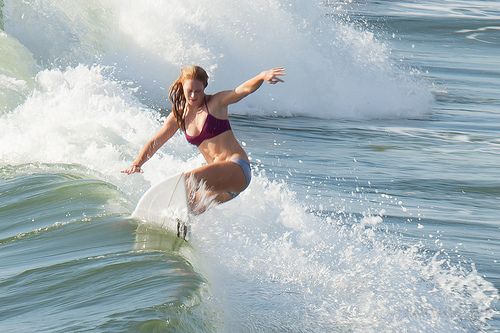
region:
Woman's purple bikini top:
[168, 107, 233, 144]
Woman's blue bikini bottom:
[211, 158, 251, 197]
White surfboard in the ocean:
[130, 170, 190, 243]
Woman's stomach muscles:
[192, 133, 232, 165]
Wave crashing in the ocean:
[27, 150, 209, 330]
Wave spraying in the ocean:
[18, 2, 441, 119]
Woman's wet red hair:
[162, 67, 208, 127]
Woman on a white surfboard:
[78, 63, 285, 237]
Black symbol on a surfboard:
[174, 215, 187, 238]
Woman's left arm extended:
[213, 66, 288, 103]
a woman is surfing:
[121, 27, 325, 306]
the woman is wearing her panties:
[110, 38, 310, 255]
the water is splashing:
[226, 175, 468, 323]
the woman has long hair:
[143, 44, 227, 121]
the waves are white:
[157, 1, 426, 128]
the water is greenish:
[57, 231, 207, 317]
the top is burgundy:
[141, 90, 237, 147]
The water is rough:
[5, 5, 458, 195]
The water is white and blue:
[75, 146, 475, 328]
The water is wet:
[96, 135, 456, 330]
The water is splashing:
[128, 173, 478, 330]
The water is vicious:
[126, 166, 433, 322]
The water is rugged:
[36, 162, 491, 322]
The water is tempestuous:
[112, 165, 492, 315]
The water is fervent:
[138, 173, 483, 328]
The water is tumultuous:
[123, 175, 488, 327]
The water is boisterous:
[120, 172, 485, 328]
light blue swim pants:
[221, 160, 250, 200]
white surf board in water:
[130, 173, 190, 243]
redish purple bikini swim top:
[181, 97, 230, 146]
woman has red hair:
[168, 64, 210, 134]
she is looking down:
[180, 78, 206, 108]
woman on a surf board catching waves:
[118, 67, 285, 238]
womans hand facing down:
[117, 165, 143, 175]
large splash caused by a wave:
[0, 2, 443, 122]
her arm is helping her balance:
[220, 68, 285, 103]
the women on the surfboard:
[117, 43, 291, 238]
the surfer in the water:
[108, 42, 290, 248]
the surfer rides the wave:
[113, 25, 288, 271]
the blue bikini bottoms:
[225, 153, 254, 204]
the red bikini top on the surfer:
[174, 103, 237, 148]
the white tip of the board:
[132, 172, 197, 240]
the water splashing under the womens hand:
[108, 143, 159, 179]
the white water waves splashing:
[270, 205, 498, 328]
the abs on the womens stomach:
[200, 138, 227, 162]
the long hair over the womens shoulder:
[170, 70, 185, 131]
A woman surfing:
[107, 48, 276, 225]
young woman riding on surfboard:
[118, 63, 287, 241]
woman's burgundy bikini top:
[178, 91, 232, 146]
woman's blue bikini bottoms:
[208, 155, 253, 198]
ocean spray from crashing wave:
[2, 0, 440, 119]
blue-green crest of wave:
[1, 164, 216, 330]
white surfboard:
[127, 170, 192, 240]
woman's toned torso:
[176, 95, 242, 160]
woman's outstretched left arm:
[212, 65, 287, 103]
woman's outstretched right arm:
[120, 107, 178, 175]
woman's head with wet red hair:
[166, 64, 210, 123]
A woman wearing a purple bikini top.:
[121, 57, 286, 242]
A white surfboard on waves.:
[127, 170, 189, 244]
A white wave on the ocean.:
[2, 65, 498, 327]